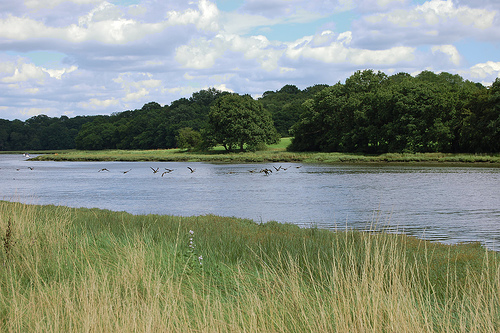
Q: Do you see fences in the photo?
A: No, there are no fences.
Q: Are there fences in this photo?
A: No, there are no fences.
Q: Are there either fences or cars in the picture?
A: No, there are no fences or cars.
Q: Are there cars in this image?
A: No, there are no cars.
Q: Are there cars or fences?
A: No, there are no cars or fences.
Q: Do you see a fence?
A: No, there are no fences.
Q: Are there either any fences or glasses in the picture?
A: No, there are no fences or glasses.